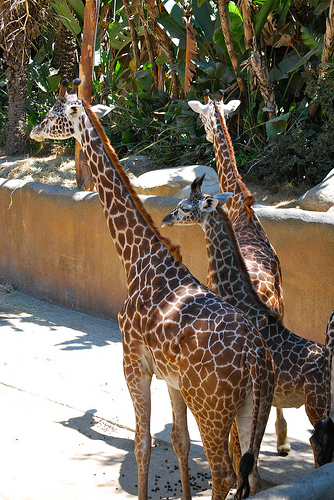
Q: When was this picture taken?
A: Daytime.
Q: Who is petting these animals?
A: No one.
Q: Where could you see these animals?
A: A zoo.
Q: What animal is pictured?
A: Giraffes.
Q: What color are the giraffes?
A: Brown and white.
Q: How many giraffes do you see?
A: 3.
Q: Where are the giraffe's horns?
A: On their heads.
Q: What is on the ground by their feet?
A: Feces.